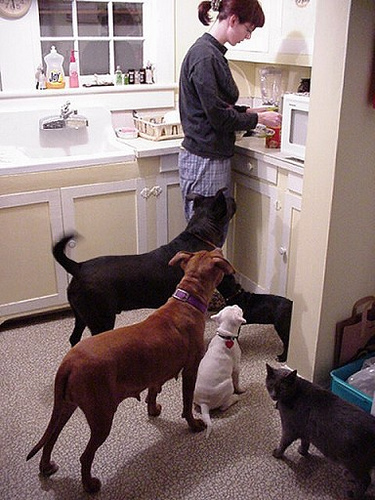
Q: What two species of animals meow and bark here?
A: Cat and dog.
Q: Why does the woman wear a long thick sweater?
A: Cold.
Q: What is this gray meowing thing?
A: Cat.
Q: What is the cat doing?
A: Standing.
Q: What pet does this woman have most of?
A: Dogs.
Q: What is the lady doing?
A: Getting food.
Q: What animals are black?
A: Dogs.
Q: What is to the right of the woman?
A: A microwave.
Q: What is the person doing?
A: Opening the can.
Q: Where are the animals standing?
A: In the kitchen.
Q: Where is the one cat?
A: Near the dogs.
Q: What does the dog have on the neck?
A: A collar.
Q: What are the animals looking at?
A: Food.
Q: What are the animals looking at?
A: Food.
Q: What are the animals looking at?
A: Food.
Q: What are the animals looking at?
A: Food.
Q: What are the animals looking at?
A: Food.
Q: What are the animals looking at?
A: Food.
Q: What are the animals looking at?
A: Food.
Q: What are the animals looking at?
A: Food.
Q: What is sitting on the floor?
A: A dog.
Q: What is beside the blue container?
A: A cat.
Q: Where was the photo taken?
A: In a kitchen.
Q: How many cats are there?
A: One.